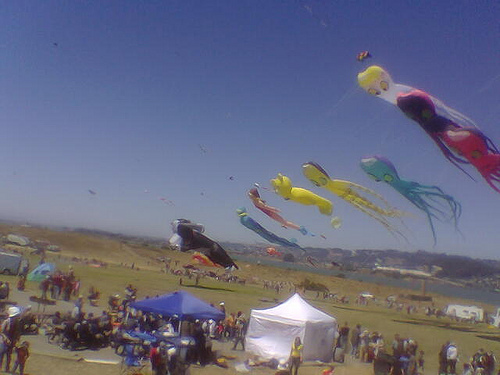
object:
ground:
[0, 222, 500, 375]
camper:
[446, 301, 487, 323]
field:
[1, 222, 494, 375]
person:
[0, 309, 23, 375]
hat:
[5, 306, 21, 317]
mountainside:
[218, 242, 500, 284]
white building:
[442, 305, 484, 324]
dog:
[168, 216, 239, 276]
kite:
[299, 160, 419, 247]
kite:
[245, 188, 308, 236]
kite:
[236, 206, 306, 256]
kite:
[356, 64, 500, 193]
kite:
[270, 172, 333, 217]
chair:
[115, 340, 155, 375]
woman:
[288, 336, 303, 374]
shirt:
[291, 342, 303, 358]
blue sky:
[0, 0, 500, 260]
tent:
[242, 292, 339, 364]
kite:
[359, 155, 466, 249]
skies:
[0, 0, 500, 260]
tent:
[129, 290, 226, 334]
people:
[349, 323, 361, 360]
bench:
[0, 227, 489, 374]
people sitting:
[79, 320, 100, 351]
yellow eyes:
[364, 170, 399, 184]